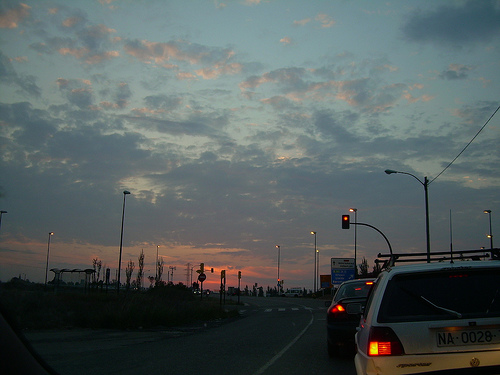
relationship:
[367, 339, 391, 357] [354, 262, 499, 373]
brake light on a car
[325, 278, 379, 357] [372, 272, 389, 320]
car has edge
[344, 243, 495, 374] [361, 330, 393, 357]
car has tail light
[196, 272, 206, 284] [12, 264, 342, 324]
sign on distance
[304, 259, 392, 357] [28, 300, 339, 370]
car driving down street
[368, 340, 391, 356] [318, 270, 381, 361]
brake light on car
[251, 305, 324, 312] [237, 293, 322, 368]
white lines on street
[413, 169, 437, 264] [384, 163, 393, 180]
pole supporting light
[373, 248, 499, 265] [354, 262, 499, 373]
roofrack on car